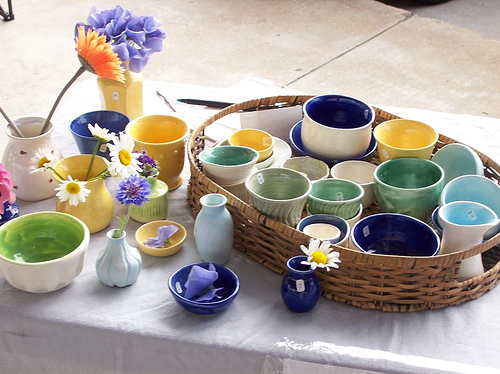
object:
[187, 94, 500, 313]
basket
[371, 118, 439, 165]
containers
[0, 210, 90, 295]
bowl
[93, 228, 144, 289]
vase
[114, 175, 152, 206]
flower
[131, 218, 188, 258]
bowl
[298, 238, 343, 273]
daisy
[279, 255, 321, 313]
container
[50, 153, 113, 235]
container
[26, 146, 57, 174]
daisy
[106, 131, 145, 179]
daisy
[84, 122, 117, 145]
daisy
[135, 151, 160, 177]
flower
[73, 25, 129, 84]
sunflower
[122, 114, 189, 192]
container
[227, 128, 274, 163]
container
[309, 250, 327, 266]
center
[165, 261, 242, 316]
bowl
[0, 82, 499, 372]
table cloth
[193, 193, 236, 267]
vase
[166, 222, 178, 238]
petal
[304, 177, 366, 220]
bowl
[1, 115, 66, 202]
vase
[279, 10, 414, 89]
crack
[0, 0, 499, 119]
sidewalk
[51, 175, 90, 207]
daisies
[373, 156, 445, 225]
vase